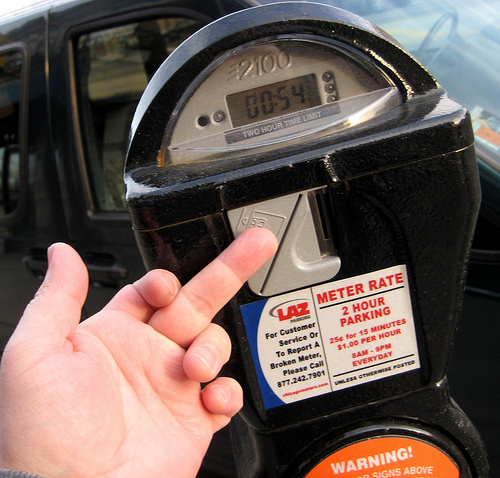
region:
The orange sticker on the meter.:
[296, 436, 461, 476]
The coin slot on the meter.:
[309, 184, 338, 264]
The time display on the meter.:
[221, 76, 328, 122]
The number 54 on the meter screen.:
[272, 89, 317, 106]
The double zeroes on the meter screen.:
[233, 89, 284, 119]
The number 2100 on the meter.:
[231, 55, 310, 76]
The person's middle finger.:
[170, 229, 274, 333]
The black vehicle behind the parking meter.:
[6, 10, 497, 243]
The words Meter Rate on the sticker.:
[317, 266, 409, 296]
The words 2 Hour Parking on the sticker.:
[333, 303, 398, 324]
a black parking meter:
[128, 13, 485, 413]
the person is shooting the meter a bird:
[38, 192, 340, 474]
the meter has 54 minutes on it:
[228, 73, 350, 140]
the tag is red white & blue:
[236, 281, 439, 415]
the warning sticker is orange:
[305, 441, 478, 476]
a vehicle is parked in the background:
[15, 25, 160, 212]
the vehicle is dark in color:
[5, 14, 150, 235]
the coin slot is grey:
[115, 2, 470, 306]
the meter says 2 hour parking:
[322, 291, 429, 347]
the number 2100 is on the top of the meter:
[233, 45, 304, 96]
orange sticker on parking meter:
[295, 433, 462, 475]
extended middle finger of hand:
[148, 224, 277, 346]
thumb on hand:
[1, 241, 91, 353]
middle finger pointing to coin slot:
[258, 190, 308, 294]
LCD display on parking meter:
[220, 72, 325, 125]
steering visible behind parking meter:
[416, 8, 467, 72]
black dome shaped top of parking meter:
[120, 3, 443, 168]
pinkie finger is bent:
[198, 377, 245, 416]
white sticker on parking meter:
[238, 262, 423, 412]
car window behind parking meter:
[65, 9, 209, 220]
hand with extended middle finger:
[3, 220, 279, 474]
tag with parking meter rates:
[246, 260, 426, 417]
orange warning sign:
[294, 429, 467, 476]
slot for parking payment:
[242, 185, 307, 303]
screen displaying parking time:
[223, 67, 324, 135]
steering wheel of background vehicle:
[408, 5, 467, 88]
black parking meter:
[118, 0, 491, 474]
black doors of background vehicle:
[2, 5, 219, 287]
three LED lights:
[322, 67, 339, 108]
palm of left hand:
[49, 348, 184, 460]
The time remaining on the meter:
[272, 72, 312, 119]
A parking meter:
[110, 9, 498, 476]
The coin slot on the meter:
[308, 189, 333, 246]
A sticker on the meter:
[242, 266, 429, 418]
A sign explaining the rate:
[306, 264, 417, 383]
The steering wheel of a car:
[407, 9, 469, 67]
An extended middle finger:
[145, 211, 284, 349]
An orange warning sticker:
[307, 423, 465, 476]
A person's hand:
[6, 221, 286, 476]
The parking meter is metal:
[120, 6, 498, 476]